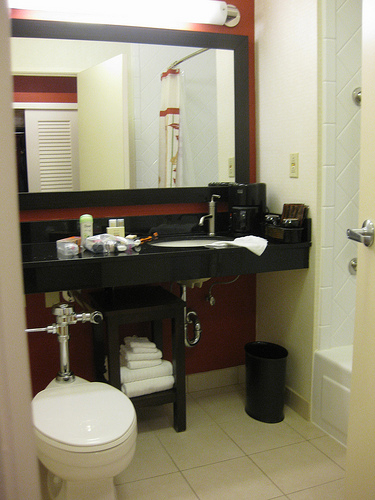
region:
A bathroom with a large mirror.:
[0, 0, 374, 499]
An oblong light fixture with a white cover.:
[6, 0, 240, 27]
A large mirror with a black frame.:
[7, 15, 247, 210]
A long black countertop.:
[16, 206, 305, 288]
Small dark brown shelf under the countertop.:
[78, 285, 183, 431]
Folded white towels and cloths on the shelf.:
[101, 336, 174, 397]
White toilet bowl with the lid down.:
[30, 373, 135, 498]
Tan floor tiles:
[30, 385, 345, 498]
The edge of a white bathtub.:
[310, 346, 349, 444]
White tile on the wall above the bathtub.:
[318, 0, 362, 349]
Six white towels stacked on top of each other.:
[102, 338, 177, 395]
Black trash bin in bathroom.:
[246, 341, 287, 423]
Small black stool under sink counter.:
[90, 284, 200, 445]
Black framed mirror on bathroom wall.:
[10, 14, 255, 206]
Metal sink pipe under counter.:
[177, 281, 204, 347]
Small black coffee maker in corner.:
[222, 180, 265, 234]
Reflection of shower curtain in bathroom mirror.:
[154, 69, 192, 192]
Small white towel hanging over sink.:
[206, 235, 268, 256]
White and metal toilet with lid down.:
[27, 309, 137, 498]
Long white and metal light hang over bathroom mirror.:
[8, 0, 246, 26]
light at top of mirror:
[7, 0, 246, 27]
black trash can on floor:
[245, 339, 292, 424]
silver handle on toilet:
[24, 326, 52, 334]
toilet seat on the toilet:
[29, 377, 134, 452]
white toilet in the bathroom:
[35, 376, 137, 498]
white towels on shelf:
[122, 330, 175, 394]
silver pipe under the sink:
[186, 286, 202, 362]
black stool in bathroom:
[95, 286, 204, 403]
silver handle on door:
[345, 220, 373, 253]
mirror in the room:
[14, 33, 235, 187]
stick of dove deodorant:
[77, 212, 95, 248]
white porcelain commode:
[29, 371, 138, 498]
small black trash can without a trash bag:
[241, 337, 290, 424]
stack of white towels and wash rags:
[100, 332, 175, 399]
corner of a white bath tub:
[307, 343, 355, 450]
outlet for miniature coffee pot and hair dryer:
[287, 149, 300, 178]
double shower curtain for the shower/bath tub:
[155, 59, 197, 190]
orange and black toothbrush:
[137, 230, 159, 243]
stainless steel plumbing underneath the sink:
[177, 282, 202, 349]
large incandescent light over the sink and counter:
[5, 0, 240, 29]